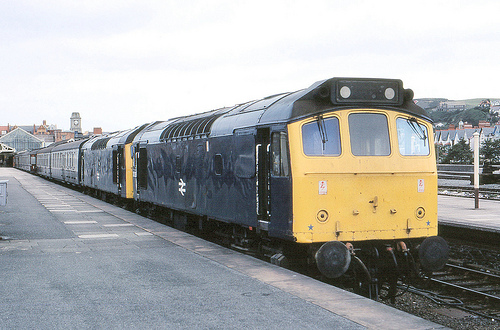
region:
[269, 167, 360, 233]
The train is visible.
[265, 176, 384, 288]
The train is visible.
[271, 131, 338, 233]
The train is visible.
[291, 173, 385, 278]
The train is visible.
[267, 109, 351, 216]
The train is visible.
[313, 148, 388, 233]
The train is visible.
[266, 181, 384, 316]
The train is visible.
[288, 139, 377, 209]
The train is visible.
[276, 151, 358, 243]
The train is visible.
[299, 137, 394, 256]
The train is visible.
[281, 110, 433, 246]
the yellow front of a train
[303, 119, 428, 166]
three windows on the front of a train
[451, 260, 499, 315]
railroad tracks beside a train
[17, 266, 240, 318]
the concrete platform to the left of the train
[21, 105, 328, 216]
multiple black train cars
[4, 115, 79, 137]
several buildings in the background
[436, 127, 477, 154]
houses on the right of the train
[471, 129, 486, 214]
a white metal pole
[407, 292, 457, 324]
gravel beside the train track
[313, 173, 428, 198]
two white stickers on the front of the train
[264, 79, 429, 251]
front of a yellow and black train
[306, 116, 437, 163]
front windows of a train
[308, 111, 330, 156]
windshield wiper of train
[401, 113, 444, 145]
right windshield wiper of train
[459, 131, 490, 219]
post on side of train platform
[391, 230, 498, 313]
train tracks next to train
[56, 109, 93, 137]
clock tower in back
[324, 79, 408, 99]
headlights on front of train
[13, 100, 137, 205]
multiple train cars attached to train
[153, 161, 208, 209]
logo on side of train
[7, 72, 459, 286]
a black with yellow colored train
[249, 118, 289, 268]
an area to get into the train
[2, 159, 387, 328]
a cement platform on left side of train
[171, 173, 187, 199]
yellow symbol on side of train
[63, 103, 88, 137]
building tower with a clock on it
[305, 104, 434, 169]
three front windows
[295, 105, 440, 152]
two black windshield wipers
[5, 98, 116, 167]
group of buildings in the distance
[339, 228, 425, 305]
black tubing on the front bottom of train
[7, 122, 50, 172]
train station building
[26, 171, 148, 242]
white rectangles in the train platform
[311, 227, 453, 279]
two round metal pieces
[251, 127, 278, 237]
the open door at the side of the train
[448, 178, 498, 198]
a train track behind a train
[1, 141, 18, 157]
a white piece of metal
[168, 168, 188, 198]
a white symbol on the side of a black train car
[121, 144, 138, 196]
a yellow divider between train cars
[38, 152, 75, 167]
a row of windows on two train cars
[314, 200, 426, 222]
two circular metal indents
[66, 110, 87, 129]
a gray building spire